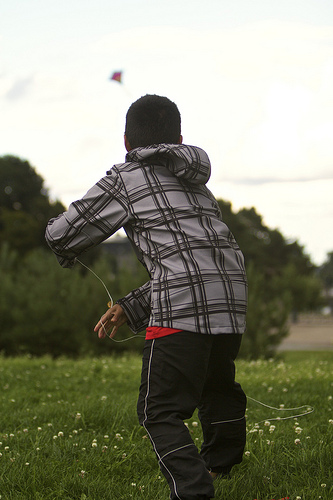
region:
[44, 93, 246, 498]
a boy flying a kite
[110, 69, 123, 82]
a red kite in the sky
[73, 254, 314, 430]
a string connected to the kite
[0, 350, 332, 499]
a green, grassy field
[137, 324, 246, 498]
black pants on the boy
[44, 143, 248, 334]
gray jacket on the boy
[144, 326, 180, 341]
red shirt under the jacket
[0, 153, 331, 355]
trees behind the field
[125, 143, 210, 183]
hood of the jacket is down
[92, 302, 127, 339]
boy's hand is holding string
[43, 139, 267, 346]
Jacket with grey plaid print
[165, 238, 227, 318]
Grey and black plaid print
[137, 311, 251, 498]
Long black sweatpants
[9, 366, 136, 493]
Grass with small white flowers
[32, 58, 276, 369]
Young boy flying a kite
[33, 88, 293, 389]
Young boy with short brown hair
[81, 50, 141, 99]
Pink, red, and yellow kite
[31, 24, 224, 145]
Kite flying in the air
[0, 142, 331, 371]
Green shrubs and trees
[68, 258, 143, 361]
hand holding a string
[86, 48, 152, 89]
Kite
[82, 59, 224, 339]
The boy is flying a kite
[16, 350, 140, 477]
The grass is covered in weeds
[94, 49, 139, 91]
The kite is shaped like a diamond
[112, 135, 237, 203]
The boy's jacket has a hood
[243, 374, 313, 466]
String of the kite on the ground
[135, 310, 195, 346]
Red shirt under the boy's jacket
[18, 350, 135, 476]
The boy is standing on grass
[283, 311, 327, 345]
Street is made of cement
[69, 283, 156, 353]
Boy is holding string in right hand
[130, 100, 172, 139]
The hair color is black.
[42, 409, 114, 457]
The grass has white flowers.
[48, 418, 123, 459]
The white flowers are dandelions.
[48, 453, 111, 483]
The grass blades are green.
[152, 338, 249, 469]
The pant color is black.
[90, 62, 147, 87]
The boy is flying a kite.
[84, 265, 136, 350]
The boy is holding a string.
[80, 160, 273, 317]
The boy is wearing a hooded pullover.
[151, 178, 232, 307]
The color of the pullover is grey and black.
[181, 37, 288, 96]
The sky is cloudy.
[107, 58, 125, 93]
A blurry red kite in the sky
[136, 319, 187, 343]
A red shirt sticking out of a jacket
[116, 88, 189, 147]
The back of a young mans head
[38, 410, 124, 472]
Green grass with poppy flowers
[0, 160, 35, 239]
Green leaves on a tree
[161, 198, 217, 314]
A Gray jacket with black stripes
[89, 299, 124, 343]
A hand with string in it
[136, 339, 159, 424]
Gray piping on black pants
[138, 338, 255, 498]
A person wearing black pants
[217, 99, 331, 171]
Overcast white cloudy skies